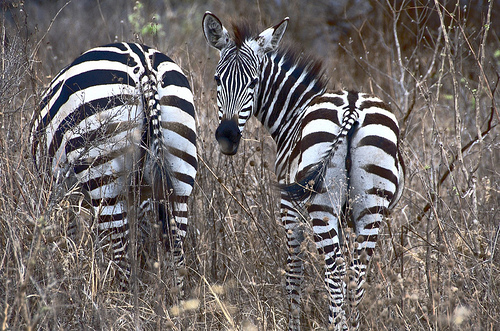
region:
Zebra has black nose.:
[217, 116, 235, 160]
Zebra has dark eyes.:
[196, 72, 304, 118]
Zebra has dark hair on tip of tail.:
[296, 152, 348, 252]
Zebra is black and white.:
[291, 116, 375, 208]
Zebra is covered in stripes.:
[281, 95, 373, 237]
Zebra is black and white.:
[61, 82, 188, 221]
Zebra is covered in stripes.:
[83, 60, 190, 195]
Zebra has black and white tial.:
[136, 65, 222, 228]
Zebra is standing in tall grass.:
[55, 231, 210, 327]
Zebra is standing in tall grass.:
[262, 169, 399, 301]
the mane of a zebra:
[228, 23, 337, 91]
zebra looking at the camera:
[190, 11, 300, 163]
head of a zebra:
[194, 8, 296, 163]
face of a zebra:
[200, 13, 296, 163]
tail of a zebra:
[279, 96, 367, 212]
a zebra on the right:
[194, 8, 405, 329]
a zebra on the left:
[14, 33, 204, 310]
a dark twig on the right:
[404, 82, 496, 239]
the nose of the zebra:
[212, 111, 241, 159]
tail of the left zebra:
[139, 64, 191, 258]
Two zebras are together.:
[17, 10, 448, 325]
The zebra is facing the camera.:
[178, 5, 303, 162]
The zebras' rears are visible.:
[22, 35, 429, 322]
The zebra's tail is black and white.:
[132, 55, 175, 197]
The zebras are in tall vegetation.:
[0, 4, 496, 329]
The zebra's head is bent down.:
[112, 175, 164, 288]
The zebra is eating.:
[110, 174, 174, 299]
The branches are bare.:
[373, 1, 498, 198]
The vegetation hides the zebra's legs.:
[54, 197, 221, 328]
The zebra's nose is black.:
[212, 106, 252, 157]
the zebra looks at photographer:
[191, 15, 428, 285]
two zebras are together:
[52, 31, 490, 268]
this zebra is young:
[187, 12, 484, 326]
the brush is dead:
[28, 17, 496, 305]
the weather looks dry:
[15, 18, 472, 289]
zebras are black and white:
[15, 30, 490, 305]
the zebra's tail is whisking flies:
[194, 1, 434, 319]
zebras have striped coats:
[18, 24, 482, 311]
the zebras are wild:
[17, 15, 479, 303]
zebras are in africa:
[48, 22, 465, 294]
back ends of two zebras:
[65, 40, 391, 215]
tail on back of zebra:
[275, 114, 357, 215]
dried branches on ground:
[410, 181, 485, 314]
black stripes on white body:
[80, 59, 124, 154]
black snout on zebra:
[215, 111, 243, 151]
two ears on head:
[196, 7, 298, 59]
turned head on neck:
[188, 11, 312, 161]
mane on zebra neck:
[289, 41, 326, 77]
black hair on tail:
[262, 163, 337, 210]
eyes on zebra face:
[210, 65, 262, 92]